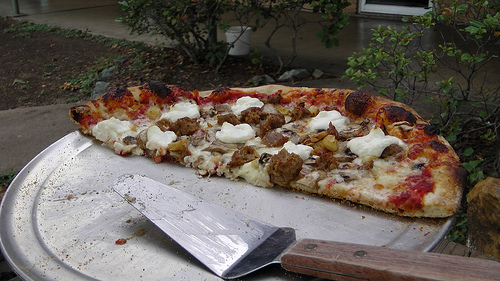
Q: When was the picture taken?
A: Daytime.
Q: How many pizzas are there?
A: One.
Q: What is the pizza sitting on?
A: A pan.